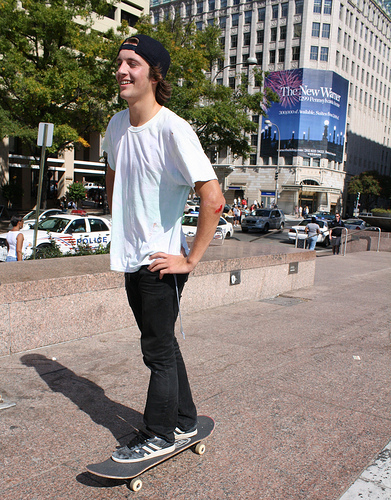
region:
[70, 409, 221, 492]
this is a skateboard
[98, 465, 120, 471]
the skateboard is black in color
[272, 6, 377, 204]
this is a building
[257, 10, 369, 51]
these are several windows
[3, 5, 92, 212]
this is a tree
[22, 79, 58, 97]
the leaves are green in color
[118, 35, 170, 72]
this is a cap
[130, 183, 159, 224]
the t-shirt is white in color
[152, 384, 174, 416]
the trouser is black in color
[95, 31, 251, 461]
this is a man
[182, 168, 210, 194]
edge of a sleeve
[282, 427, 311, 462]
part of a floor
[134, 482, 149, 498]
part of a wheel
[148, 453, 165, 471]
edge of a board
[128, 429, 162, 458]
part of a shoe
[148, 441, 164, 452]
edge of a shoe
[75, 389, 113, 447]
part of a shade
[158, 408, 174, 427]
part of a trouser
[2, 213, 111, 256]
white police car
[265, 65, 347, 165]
Banner attached to building.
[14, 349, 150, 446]
Boys shadow on ground.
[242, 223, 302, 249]
Handrail for stairs.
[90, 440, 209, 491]
White wheels on skateboard.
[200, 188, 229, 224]
Open cut on boys elbow.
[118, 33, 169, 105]
Boy wearing baseball cap backwards.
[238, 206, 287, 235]
Silver SUV on road.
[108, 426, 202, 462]
White soles on sneakers.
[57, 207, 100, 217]
Red light on roof of police car.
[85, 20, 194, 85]
man is wearing black hat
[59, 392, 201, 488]
the skateboard is black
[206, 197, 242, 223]
man's elbow is bleeding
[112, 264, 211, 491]
man's jeans are black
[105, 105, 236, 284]
man's shirt is white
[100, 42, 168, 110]
the man is smiling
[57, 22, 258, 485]
the man is skateboarding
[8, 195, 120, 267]
police car in background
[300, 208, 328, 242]
woman wearing gray shirt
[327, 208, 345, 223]
man is wearing sunglasses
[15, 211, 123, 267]
A police car on the road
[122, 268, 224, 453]
The man wears black pants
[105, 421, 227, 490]
A black skateboard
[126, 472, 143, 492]
A white wheel on the skateboard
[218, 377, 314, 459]
Grey concrete under the skateboard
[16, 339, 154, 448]
The skater's shadow on the ground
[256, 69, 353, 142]
An advertisement on the building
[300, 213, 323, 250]
A man with a grey shirt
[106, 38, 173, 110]
The boy has long hair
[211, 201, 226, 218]
The boy has scarped his elbow